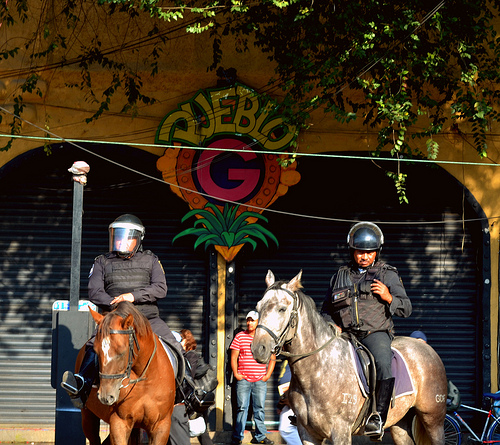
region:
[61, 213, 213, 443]
a police officer riding a horse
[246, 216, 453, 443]
a police officer riding a horse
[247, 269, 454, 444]
a horse with a purple saddle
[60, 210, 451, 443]
two police officer riding horses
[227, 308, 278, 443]
a man wearing a red and white striped shirt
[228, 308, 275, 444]
a man wearing blue jeans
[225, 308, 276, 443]
a man wearing a white hat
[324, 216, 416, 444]
a police officer wearing a black jacket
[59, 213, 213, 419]
a police officer wearing a black jacket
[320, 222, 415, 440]
a police officer wearing black pants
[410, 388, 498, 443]
gray mountain bike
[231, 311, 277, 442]
a man wearing a hat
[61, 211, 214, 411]
man sitting on a horse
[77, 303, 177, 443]
horse with a brown mane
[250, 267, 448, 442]
horse with a black mane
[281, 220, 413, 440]
man wearing a helmet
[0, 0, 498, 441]
large yellow building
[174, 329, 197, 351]
person with red hair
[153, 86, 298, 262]
sign attached to the building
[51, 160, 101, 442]
a black pay phone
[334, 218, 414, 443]
A man on top of a horse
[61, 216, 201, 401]
A man on top of a horse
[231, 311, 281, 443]
A man in blue jeans standing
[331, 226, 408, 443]
A man in a helmet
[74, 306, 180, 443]
A brown horse with a man on top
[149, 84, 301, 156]
A sign with the name PUEBLO written on it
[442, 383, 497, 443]
A bicycle parked behind the horse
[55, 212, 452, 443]
Two men on top of two horses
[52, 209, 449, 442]
Two men with helmets in their heads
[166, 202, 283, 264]
A green plantation hanging from a canopy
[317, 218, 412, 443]
Policeman in protective gear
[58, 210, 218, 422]
Policeman with helmet and protective gear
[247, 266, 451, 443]
Dappled brown and white horse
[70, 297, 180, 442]
Horse with a white blaze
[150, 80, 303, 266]
Colorful Pueblo G sign with a green plant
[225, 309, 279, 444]
Man in red and white striped shirt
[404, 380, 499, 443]
Blue and white bike with red markings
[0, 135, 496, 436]
Two black shuttered archways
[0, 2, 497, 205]
Hanging green foliage with vines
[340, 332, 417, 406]
Purple horse blanket with white border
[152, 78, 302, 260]
the Pueblo G sign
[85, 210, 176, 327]
the officer with the face shield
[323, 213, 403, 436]
the officer without his face shield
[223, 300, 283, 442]
man wearing the red and white striped shirt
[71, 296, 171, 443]
the reddish-brown horse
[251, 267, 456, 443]
the white and tan spotted horse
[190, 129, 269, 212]
a large red "G"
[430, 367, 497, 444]
the bicycle parked against the building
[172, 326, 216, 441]
the red haired lady behind the horse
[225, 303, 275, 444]
the man wearing a white baseball hat and jeans